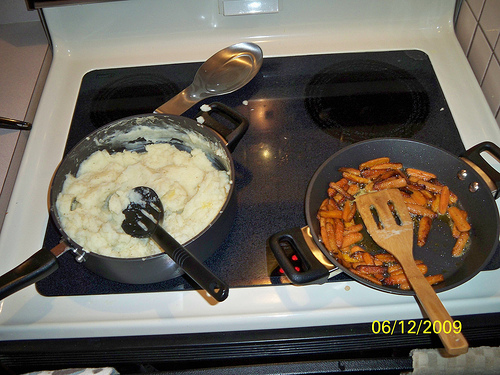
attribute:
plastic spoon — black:
[126, 234, 242, 314]